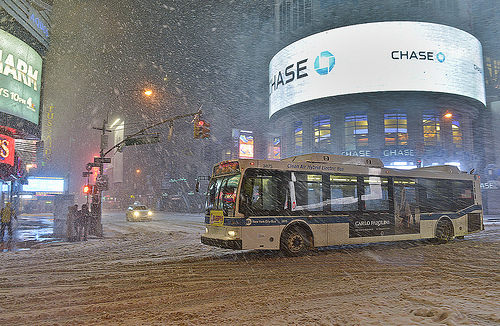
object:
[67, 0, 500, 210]
building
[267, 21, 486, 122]
sign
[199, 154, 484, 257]
bus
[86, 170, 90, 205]
pole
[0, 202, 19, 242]
people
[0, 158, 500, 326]
streets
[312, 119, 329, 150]
windows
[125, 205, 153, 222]
car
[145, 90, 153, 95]
light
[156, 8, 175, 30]
snow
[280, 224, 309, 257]
tire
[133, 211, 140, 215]
headlight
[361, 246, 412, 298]
ground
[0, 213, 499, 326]
road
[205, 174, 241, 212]
windshield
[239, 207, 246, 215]
mirror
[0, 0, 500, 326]
city